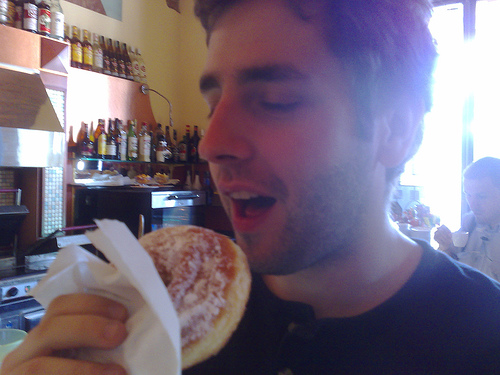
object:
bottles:
[62, 22, 147, 85]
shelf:
[65, 65, 160, 135]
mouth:
[218, 179, 281, 233]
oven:
[0, 166, 64, 315]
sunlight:
[396, 0, 499, 230]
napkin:
[28, 217, 184, 374]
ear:
[374, 85, 422, 169]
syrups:
[74, 117, 200, 162]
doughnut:
[122, 216, 252, 368]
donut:
[129, 223, 251, 369]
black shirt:
[180, 237, 500, 374]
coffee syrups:
[63, 21, 148, 84]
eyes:
[199, 79, 303, 119]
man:
[0, 0, 500, 375]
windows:
[386, 3, 499, 248]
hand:
[0, 287, 135, 375]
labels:
[70, 42, 93, 65]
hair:
[191, 0, 431, 186]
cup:
[451, 233, 468, 248]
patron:
[433, 156, 499, 280]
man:
[433, 155, 499, 290]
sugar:
[169, 241, 225, 343]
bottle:
[114, 118, 128, 161]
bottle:
[128, 120, 140, 161]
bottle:
[97, 119, 107, 159]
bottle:
[76, 124, 96, 158]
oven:
[74, 188, 207, 237]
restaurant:
[0, 0, 500, 375]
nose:
[196, 89, 252, 164]